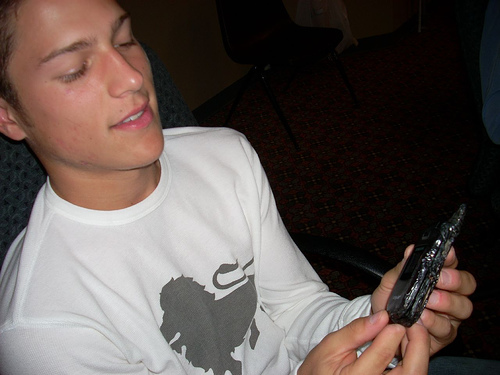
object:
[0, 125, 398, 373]
shirt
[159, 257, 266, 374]
lion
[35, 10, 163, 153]
face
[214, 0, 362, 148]
chair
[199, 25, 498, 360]
carpet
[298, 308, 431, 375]
hand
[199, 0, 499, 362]
ground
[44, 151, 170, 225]
collar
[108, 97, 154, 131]
mouth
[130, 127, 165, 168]
chin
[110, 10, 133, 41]
left eyebrow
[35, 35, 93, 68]
right eyebrow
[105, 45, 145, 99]
nose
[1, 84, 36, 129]
side burn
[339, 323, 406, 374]
finger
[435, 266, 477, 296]
finger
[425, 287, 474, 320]
finger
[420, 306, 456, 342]
finger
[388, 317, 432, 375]
finger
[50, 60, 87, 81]
eye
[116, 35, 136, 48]
eye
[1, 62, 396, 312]
chair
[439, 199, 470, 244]
antenna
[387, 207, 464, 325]
phone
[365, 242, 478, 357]
hand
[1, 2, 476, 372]
boy